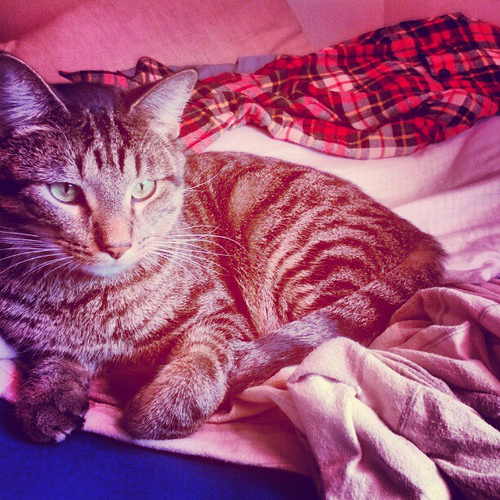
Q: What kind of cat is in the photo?
A: A tabby.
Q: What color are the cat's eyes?
A: Green.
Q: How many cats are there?
A: One.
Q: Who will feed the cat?
A: The owner.